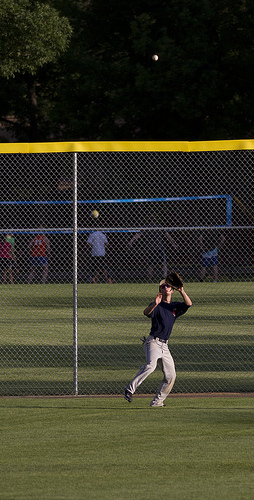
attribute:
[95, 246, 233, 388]
player — trying, wearing, playing, catcher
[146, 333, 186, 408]
pants — grey, white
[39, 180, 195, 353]
fence — behind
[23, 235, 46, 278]
shirt — orange, white, green, red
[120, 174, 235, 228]
net — behind, blue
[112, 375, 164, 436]
foot — above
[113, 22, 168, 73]
ball — flying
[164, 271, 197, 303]
mitt — catching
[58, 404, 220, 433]
grass — green, present, here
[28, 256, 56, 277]
shorts — blue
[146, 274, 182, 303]
face — wearing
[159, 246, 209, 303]
glove — leather, here, present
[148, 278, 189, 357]
shirt — black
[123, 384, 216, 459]
shoes — black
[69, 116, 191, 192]
marker — yellow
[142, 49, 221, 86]
baseball — white